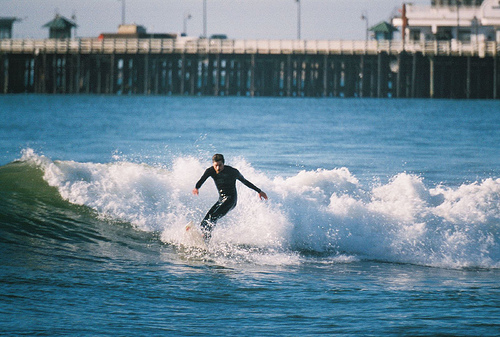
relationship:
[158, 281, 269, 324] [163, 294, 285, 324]
waves in water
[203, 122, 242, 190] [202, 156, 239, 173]
hair on mans head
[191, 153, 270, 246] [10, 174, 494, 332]
male surfing in water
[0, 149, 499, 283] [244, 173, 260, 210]
surfing mans left hand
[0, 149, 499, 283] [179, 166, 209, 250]
surfing mans right hand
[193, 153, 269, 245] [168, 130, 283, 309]
surfer worn by man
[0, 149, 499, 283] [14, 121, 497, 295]
surfing calm blue body of water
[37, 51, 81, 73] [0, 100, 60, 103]
shelter on land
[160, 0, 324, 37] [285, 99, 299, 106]
clouds in sky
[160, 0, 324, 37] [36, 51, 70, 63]
clouds in sky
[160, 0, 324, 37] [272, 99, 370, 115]
clouds in sky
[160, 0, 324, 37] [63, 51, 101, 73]
clouds in sky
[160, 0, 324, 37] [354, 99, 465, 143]
clouds in sky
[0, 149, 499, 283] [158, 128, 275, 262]
surfing man surfing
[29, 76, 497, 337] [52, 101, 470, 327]
surfing by pier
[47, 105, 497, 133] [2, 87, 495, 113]
fence on pier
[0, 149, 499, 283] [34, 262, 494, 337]
surfing surfer by pier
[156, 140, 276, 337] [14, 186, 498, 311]
surfer cresting a wave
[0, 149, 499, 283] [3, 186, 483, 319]
surfing waves are white capped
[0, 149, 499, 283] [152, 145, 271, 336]
surfing surfer male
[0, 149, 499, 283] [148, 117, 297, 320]
surfing sport surfing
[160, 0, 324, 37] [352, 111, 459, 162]
clouds in sky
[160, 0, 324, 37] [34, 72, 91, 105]
clouds in sky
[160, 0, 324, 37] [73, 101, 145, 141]
clouds in sky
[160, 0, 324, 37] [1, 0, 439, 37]
clouds in sky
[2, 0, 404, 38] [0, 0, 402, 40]
clouds in sky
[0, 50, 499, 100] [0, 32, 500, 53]
pillar on pier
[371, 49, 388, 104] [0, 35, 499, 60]
pillar on pier